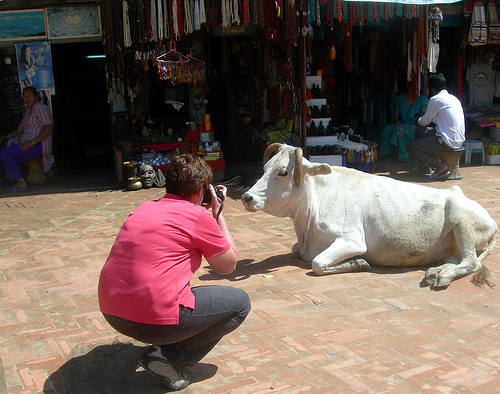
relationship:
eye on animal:
[282, 170, 292, 178] [240, 143, 496, 290]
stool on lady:
[22, 159, 47, 186] [4, 87, 54, 192]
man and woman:
[404, 72, 467, 173] [376, 80, 428, 158]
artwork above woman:
[13, 37, 58, 97] [2, 85, 54, 182]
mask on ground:
[139, 164, 156, 189] [9, 189, 113, 242]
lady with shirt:
[0, 87, 54, 192] [118, 157, 247, 357]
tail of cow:
[464, 229, 498, 299] [232, 136, 477, 293]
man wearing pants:
[95, 152, 251, 387] [103, 270, 263, 387]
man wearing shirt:
[397, 48, 473, 172] [415, 83, 470, 143]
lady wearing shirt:
[0, 87, 54, 192] [10, 100, 57, 147]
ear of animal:
[304, 160, 331, 177] [240, 143, 496, 290]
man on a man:
[95, 143, 252, 388] [401, 76, 472, 176]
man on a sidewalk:
[95, 143, 252, 388] [22, 160, 484, 390]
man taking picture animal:
[95, 143, 252, 388] [230, 120, 484, 282]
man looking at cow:
[95, 143, 252, 388] [240, 133, 500, 295]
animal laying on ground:
[240, 143, 496, 290] [255, 152, 496, 304]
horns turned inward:
[260, 138, 304, 184] [259, 108, 319, 175]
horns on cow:
[252, 122, 323, 238] [240, 133, 500, 295]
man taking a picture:
[95, 152, 251, 387] [23, 148, 419, 318]